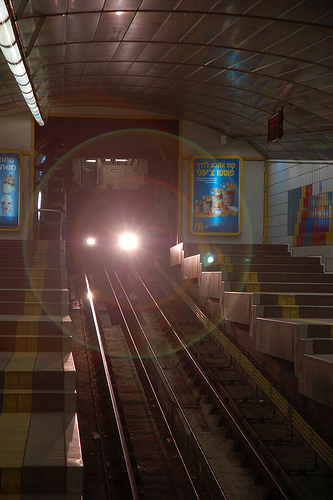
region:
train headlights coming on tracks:
[76, 201, 192, 306]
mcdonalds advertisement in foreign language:
[185, 135, 253, 253]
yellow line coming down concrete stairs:
[6, 231, 67, 468]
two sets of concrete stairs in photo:
[8, 229, 328, 466]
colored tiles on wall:
[291, 176, 330, 254]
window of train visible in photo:
[82, 151, 153, 194]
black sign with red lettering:
[251, 107, 291, 162]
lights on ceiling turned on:
[21, 102, 49, 136]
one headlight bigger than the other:
[58, 199, 160, 280]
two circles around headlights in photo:
[14, 126, 256, 364]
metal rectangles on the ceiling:
[90, 7, 279, 95]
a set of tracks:
[77, 271, 251, 452]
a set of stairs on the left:
[15, 235, 65, 481]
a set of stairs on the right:
[181, 233, 327, 345]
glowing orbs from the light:
[30, 164, 262, 359]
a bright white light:
[105, 213, 153, 266]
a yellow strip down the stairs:
[17, 248, 52, 336]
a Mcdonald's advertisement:
[184, 152, 246, 236]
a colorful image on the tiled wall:
[282, 181, 331, 242]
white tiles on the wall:
[270, 165, 290, 192]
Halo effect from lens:
[14, 117, 275, 366]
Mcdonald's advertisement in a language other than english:
[184, 145, 245, 252]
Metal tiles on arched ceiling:
[14, 5, 314, 159]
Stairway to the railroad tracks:
[1, 201, 110, 494]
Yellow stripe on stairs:
[180, 227, 313, 344]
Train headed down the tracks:
[72, 214, 313, 498]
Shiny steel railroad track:
[62, 245, 152, 487]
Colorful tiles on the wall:
[282, 193, 331, 251]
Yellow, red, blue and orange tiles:
[280, 192, 330, 250]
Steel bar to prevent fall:
[26, 186, 67, 246]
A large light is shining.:
[99, 224, 150, 263]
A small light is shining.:
[72, 226, 101, 255]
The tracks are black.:
[97, 405, 190, 480]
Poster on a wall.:
[187, 152, 245, 236]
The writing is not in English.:
[191, 154, 239, 181]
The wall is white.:
[246, 172, 263, 221]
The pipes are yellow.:
[249, 155, 269, 214]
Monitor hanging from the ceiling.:
[261, 108, 285, 145]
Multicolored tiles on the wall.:
[281, 186, 331, 237]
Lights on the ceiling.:
[7, 43, 53, 125]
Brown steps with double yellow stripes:
[195, 240, 332, 350]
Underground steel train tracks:
[83, 256, 211, 497]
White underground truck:
[73, 157, 153, 254]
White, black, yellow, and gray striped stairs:
[2, 233, 83, 494]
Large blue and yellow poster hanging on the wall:
[188, 150, 247, 238]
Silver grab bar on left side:
[31, 205, 64, 239]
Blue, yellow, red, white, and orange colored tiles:
[284, 181, 332, 249]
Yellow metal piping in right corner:
[262, 161, 271, 243]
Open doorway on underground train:
[81, 156, 99, 190]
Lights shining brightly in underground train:
[83, 157, 131, 164]